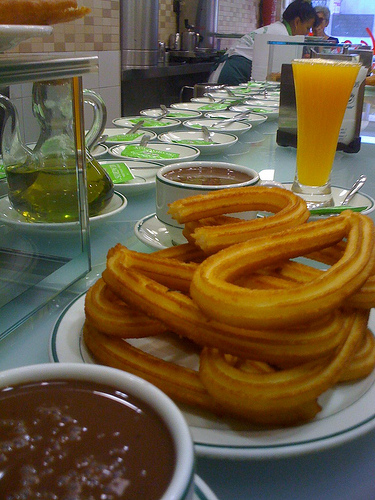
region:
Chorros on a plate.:
[49, 173, 374, 463]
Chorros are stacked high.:
[81, 180, 374, 421]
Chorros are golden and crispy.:
[62, 184, 374, 425]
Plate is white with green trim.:
[49, 228, 374, 469]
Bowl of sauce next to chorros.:
[1, 359, 198, 497]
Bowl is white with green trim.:
[145, 152, 268, 247]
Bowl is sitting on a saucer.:
[125, 207, 277, 261]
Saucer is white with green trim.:
[132, 207, 273, 257]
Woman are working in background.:
[205, 1, 341, 87]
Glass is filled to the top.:
[268, 51, 363, 205]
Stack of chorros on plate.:
[52, 184, 373, 465]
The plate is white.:
[47, 260, 371, 459]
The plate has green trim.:
[46, 250, 373, 456]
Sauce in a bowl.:
[0, 352, 202, 498]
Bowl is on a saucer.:
[0, 354, 221, 498]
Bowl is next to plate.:
[0, 361, 200, 499]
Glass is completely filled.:
[280, 46, 365, 208]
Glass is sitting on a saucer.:
[258, 170, 374, 232]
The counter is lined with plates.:
[59, 66, 297, 199]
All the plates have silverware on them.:
[71, 65, 302, 197]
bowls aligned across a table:
[91, 65, 276, 158]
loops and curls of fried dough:
[78, 180, 363, 399]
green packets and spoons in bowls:
[112, 110, 233, 165]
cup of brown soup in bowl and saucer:
[131, 150, 272, 255]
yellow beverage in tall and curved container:
[285, 41, 361, 206]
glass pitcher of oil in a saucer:
[2, 52, 129, 232]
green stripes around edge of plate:
[199, 390, 368, 465]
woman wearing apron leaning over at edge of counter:
[195, 0, 317, 91]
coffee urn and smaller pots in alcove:
[120, 15, 214, 79]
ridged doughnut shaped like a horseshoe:
[165, 176, 313, 251]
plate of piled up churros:
[146, 198, 339, 386]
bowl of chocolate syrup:
[10, 339, 188, 477]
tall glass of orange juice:
[297, 32, 360, 197]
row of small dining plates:
[121, 70, 275, 132]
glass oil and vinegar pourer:
[34, 51, 136, 212]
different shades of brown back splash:
[82, 22, 121, 40]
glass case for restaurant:
[27, 235, 85, 284]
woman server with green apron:
[201, 18, 306, 69]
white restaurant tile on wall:
[104, 61, 122, 105]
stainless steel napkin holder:
[271, 62, 300, 139]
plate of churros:
[90, 185, 373, 416]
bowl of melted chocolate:
[11, 327, 181, 498]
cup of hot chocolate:
[136, 146, 320, 256]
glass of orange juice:
[279, 43, 374, 218]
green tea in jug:
[8, 66, 141, 239]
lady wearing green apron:
[186, 0, 333, 94]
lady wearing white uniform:
[210, 0, 373, 91]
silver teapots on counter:
[170, 15, 219, 70]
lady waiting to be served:
[287, 2, 361, 56]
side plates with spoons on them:
[109, 50, 296, 194]